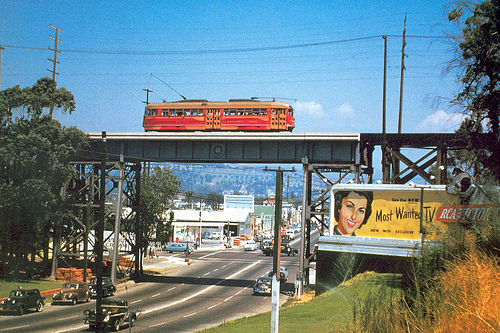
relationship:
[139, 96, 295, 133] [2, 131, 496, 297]
car on bridge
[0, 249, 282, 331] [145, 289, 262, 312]
lines on road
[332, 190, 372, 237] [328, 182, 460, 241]
woman on billboard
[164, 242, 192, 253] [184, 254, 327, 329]
car on on road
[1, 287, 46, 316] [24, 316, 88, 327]
car on side of road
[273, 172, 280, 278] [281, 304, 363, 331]
telephone pole on grass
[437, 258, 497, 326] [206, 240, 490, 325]
grass in field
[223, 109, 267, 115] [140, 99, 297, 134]
people riding red train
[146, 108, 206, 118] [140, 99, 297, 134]
people riding red train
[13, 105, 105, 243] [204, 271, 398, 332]
green trees in foreground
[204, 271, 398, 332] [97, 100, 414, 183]
foreground in front of overpass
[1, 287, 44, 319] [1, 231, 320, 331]
car on side of road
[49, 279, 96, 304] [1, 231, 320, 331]
car on side of road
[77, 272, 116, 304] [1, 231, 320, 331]
car on side of road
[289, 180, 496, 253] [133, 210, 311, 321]
billboard on side of road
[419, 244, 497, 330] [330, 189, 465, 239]
orange foliage on front of billboard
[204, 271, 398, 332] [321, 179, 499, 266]
foreground in front of billboard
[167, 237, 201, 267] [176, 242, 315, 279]
car in intersection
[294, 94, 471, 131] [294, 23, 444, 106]
clouds in sky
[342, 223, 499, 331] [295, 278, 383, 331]
foliage in foreground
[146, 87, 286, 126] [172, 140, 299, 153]
car on bridge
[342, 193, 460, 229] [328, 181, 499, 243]
advertisement on billboard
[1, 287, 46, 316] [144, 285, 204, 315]
car on road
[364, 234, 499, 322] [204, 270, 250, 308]
weeds on road